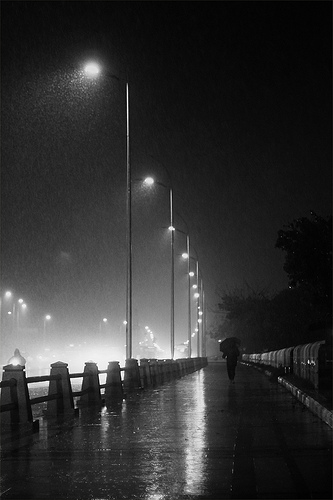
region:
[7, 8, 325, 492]
A black and white photo.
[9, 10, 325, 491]
A scene during the nighttime.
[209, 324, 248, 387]
A person with the umbrella.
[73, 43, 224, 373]
A row of streetlamps.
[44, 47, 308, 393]
A rainy day.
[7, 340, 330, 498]
A sidewalk with a person.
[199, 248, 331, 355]
A group of trees.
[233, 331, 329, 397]
A row of posts.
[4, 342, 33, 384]
A person with a hood.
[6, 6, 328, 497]
An image at dark.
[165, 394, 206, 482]
light reflecting on the street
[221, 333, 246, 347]
an umbrella sheltering a person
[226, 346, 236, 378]
a person wearing a dark coat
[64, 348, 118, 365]
white mist rising into the air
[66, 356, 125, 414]
a stone columns along a bridge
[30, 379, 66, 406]
metal poles between the columns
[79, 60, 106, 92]
a bright street light shining down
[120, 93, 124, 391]
a tall metal pole supporting the street light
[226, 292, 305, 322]
trees hanging over the street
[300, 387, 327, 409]
a cement riser on the side of the road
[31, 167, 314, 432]
Night time picture.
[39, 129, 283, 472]
It is raining heavily.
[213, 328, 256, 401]
One man is walking in the sidewalk.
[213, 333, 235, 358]
Man is holding the umbrella.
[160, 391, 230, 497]
Light reflection is seen in road.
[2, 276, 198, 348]
Lights are on.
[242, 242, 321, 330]
Trees are in sides of the road.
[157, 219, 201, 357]
Lights are attached to the pole.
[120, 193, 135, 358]
Pole is grey color.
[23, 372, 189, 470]
Roads are wet.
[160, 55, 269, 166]
Sky is black color.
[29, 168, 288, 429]
It is raining heavily.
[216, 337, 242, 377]
One man is walking in sidewalk.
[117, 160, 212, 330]
Street lamps are on.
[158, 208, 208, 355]
Lamps are attached to the pole.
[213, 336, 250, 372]
Man is holding umbrella.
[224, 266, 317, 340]
Trees are in the sides of the road.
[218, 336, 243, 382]
A person with an umbrella walking on a rainy night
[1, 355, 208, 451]
A barrier between the sidewalk and the road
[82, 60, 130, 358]
An activated lightpost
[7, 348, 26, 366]
A person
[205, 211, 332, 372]
Trees in the dark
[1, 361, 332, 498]
A wide sidewalk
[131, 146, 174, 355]
An active street light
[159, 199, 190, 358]
An active street light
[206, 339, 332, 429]
A barrier next to a sidewalk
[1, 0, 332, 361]
A rainy night sky